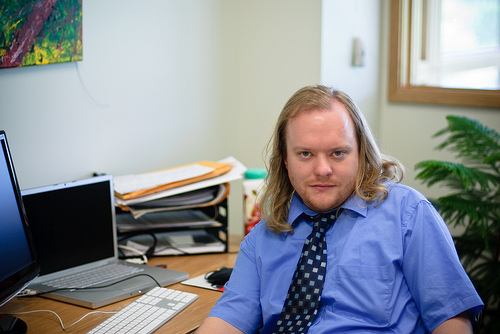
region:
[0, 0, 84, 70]
a picture on a wall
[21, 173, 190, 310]
a silver keyboard on a desk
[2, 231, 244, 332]
a wooden desk top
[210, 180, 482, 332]
a blue shirt on a man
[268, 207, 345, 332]
a blue patterned tie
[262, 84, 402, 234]
long blond hair on a man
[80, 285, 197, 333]
a white keyboard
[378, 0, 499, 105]
a window behind a man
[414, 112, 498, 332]
a plant behind a man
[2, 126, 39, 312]
a black monitor on a desk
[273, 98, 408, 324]
man is posing for a picture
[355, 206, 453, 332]
the shirt is blue in color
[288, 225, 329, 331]
the tie is black blue in color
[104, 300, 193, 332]
key board is white in color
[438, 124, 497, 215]
plants are green in color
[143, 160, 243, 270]
a pile of aranged files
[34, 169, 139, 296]
laptop is open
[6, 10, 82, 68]
a picture frame on the wall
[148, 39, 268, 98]
wall is white in color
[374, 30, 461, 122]
the mirror frame is wooden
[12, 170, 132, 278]
a computer monitor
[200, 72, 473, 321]
a man with a blue shirt and a tie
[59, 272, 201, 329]
a computer keyboard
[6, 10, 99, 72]
a picture on the wall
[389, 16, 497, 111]
a portion of a window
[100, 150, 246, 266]
stacked files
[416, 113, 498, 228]
a green leafy plant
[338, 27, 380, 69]
a thermostat on the wall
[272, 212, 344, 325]
a dark tie with lighter check boxes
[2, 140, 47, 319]
a portion of a computer monitor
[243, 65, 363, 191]
man has brown hair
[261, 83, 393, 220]
man has long hair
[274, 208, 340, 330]
blue and grey tie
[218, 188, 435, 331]
man has blue shirt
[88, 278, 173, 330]
white keyboard on table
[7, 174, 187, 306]
grey laptop on table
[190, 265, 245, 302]
white mousepad near laptop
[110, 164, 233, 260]
black paper file near laptop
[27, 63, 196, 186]
white wall behind laptop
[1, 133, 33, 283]
black monitor on table